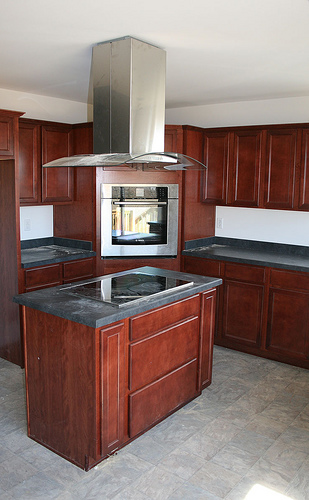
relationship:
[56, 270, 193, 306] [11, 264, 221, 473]
cooking surface on a island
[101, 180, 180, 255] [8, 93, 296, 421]
oven in kitchen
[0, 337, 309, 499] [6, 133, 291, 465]
tile floor in kitchen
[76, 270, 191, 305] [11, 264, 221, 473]
range top in island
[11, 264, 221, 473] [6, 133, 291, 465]
island in kitchen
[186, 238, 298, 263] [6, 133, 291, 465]
counter space in kitchen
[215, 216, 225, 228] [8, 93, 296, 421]
outlet in kitchen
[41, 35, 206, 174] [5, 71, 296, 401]
hood in kitchen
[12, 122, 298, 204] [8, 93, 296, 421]
cabinets in kitchen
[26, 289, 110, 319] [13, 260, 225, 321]
dust on cooking surface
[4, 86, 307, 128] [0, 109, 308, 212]
wall above cabinet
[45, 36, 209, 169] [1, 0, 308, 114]
vent attached to ceiling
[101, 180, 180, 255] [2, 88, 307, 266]
oven into wall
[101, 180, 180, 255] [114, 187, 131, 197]
oven has buttons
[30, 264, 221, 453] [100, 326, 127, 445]
island has a door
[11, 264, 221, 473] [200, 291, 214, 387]
island has a cupboard door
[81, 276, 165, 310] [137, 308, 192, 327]
cook top has a top drawer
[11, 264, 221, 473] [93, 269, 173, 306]
island has a stove